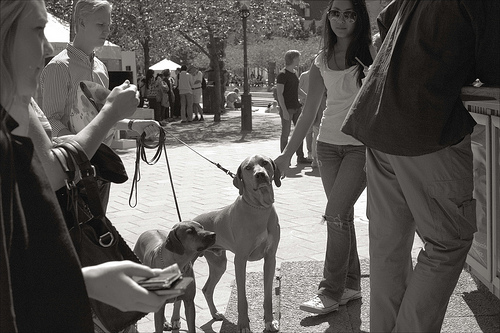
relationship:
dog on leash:
[193, 152, 284, 329] [131, 124, 239, 211]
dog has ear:
[193, 152, 284, 329] [266, 157, 283, 186]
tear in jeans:
[322, 212, 354, 228] [307, 138, 372, 303]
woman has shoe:
[271, 2, 382, 312] [293, 295, 344, 317]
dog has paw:
[193, 152, 284, 329] [233, 316, 254, 331]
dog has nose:
[193, 152, 284, 329] [252, 169, 271, 189]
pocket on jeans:
[424, 176, 480, 246] [358, 139, 476, 332]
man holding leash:
[34, 2, 165, 170] [131, 124, 239, 211]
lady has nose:
[2, 2, 89, 331] [43, 36, 55, 65]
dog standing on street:
[193, 152, 284, 329] [10, 131, 437, 328]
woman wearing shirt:
[271, 2, 382, 312] [309, 47, 378, 147]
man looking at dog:
[34, 2, 165, 170] [193, 152, 284, 329]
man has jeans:
[349, 4, 500, 332] [358, 139, 476, 332]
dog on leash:
[135, 224, 219, 328] [131, 124, 239, 211]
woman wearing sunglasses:
[271, 2, 382, 312] [326, 6, 358, 18]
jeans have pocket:
[358, 139, 476, 332] [424, 176, 480, 246]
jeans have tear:
[307, 138, 372, 303] [322, 212, 354, 228]